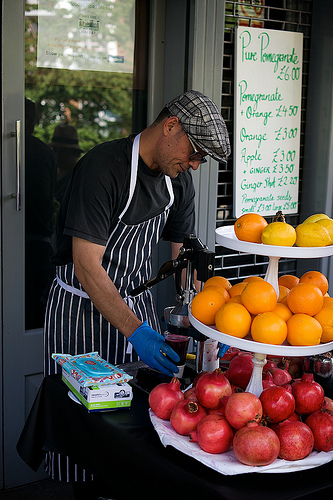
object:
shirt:
[55, 133, 196, 265]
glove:
[125, 319, 180, 379]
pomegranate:
[224, 390, 263, 429]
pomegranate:
[258, 385, 296, 424]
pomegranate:
[232, 419, 281, 467]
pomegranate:
[148, 376, 184, 420]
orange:
[190, 290, 229, 326]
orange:
[233, 213, 269, 245]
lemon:
[261, 222, 297, 247]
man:
[42, 89, 230, 500]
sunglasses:
[181, 124, 208, 165]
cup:
[201, 338, 220, 374]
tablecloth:
[15, 366, 333, 500]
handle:
[130, 246, 189, 298]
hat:
[165, 89, 230, 164]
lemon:
[295, 220, 332, 248]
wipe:
[50, 351, 133, 414]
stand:
[149, 224, 333, 477]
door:
[0, 0, 159, 492]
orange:
[240, 279, 277, 314]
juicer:
[130, 232, 220, 376]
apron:
[42, 132, 174, 377]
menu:
[35, 0, 137, 76]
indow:
[21, 0, 137, 331]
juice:
[162, 331, 192, 368]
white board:
[232, 25, 304, 222]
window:
[215, 0, 310, 279]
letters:
[239, 30, 299, 73]